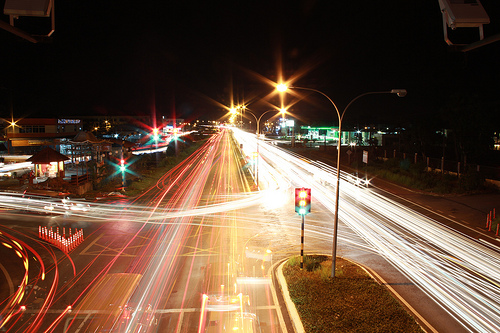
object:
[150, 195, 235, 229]
lights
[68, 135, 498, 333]
road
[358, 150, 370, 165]
sign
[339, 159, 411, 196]
ground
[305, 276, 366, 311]
grass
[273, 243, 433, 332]
median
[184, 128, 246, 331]
lanes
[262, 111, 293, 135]
buildings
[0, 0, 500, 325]
background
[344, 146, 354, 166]
pole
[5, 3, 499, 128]
sky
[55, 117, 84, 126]
words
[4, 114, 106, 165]
building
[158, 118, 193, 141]
sign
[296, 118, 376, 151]
gas station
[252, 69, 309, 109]
street light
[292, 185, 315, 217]
stop light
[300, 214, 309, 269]
pole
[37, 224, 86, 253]
street cones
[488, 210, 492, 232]
street cones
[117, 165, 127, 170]
light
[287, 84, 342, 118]
poles